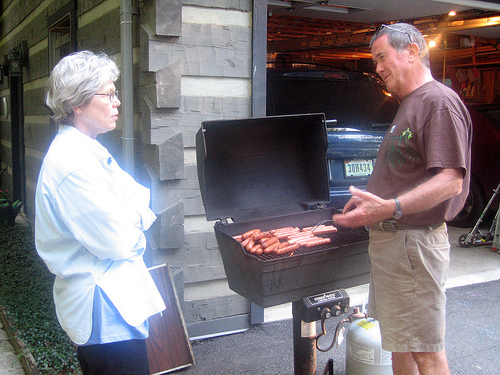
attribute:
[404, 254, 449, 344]
shorts — tan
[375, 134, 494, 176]
t-shirt — dark lavender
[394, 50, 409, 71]
hair — grey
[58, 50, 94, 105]
hair — grey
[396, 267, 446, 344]
shorts — khaki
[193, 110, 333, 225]
grill lid — black, metal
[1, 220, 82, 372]
area — green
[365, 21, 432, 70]
hair — gray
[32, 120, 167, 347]
shirt — white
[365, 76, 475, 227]
shirt — brown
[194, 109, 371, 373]
grill — black